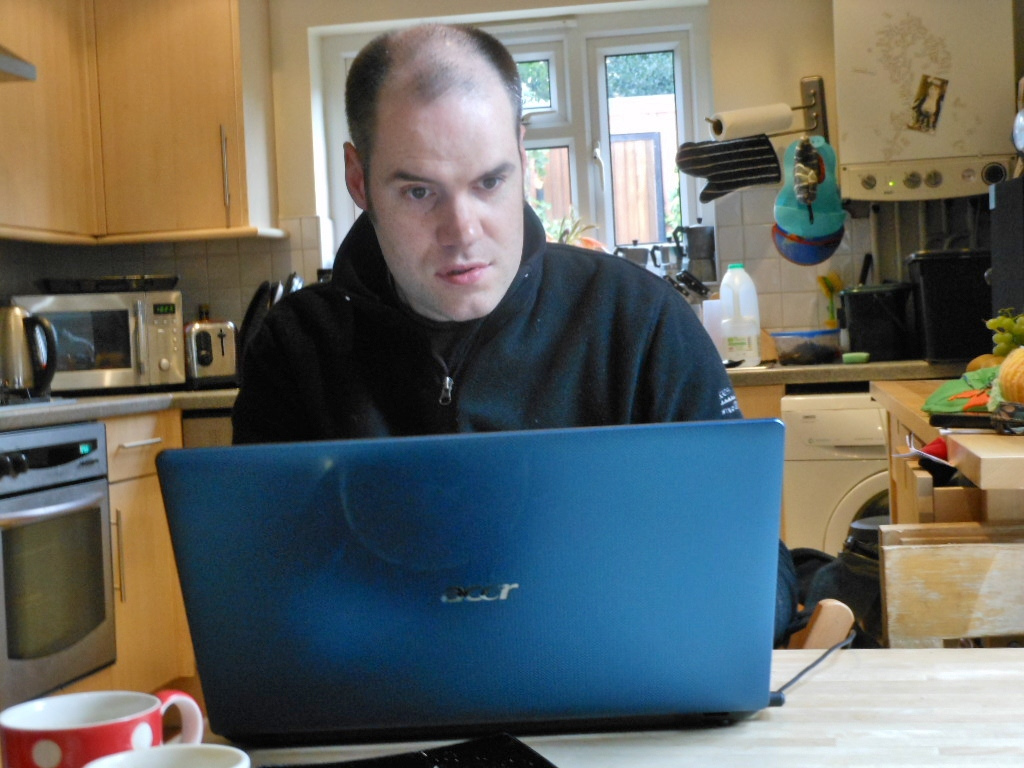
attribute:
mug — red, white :
[9, 670, 204, 764]